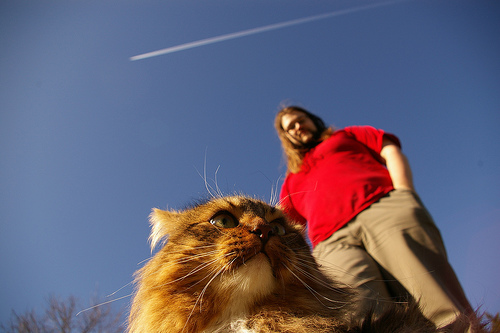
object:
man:
[276, 104, 479, 332]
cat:
[126, 198, 348, 332]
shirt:
[279, 126, 400, 250]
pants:
[299, 190, 478, 333]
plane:
[129, 55, 141, 61]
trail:
[131, 7, 383, 62]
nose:
[250, 217, 276, 239]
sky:
[1, 1, 500, 333]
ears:
[147, 205, 179, 242]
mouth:
[237, 241, 283, 270]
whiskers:
[71, 241, 414, 317]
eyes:
[210, 211, 236, 228]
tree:
[3, 295, 115, 332]